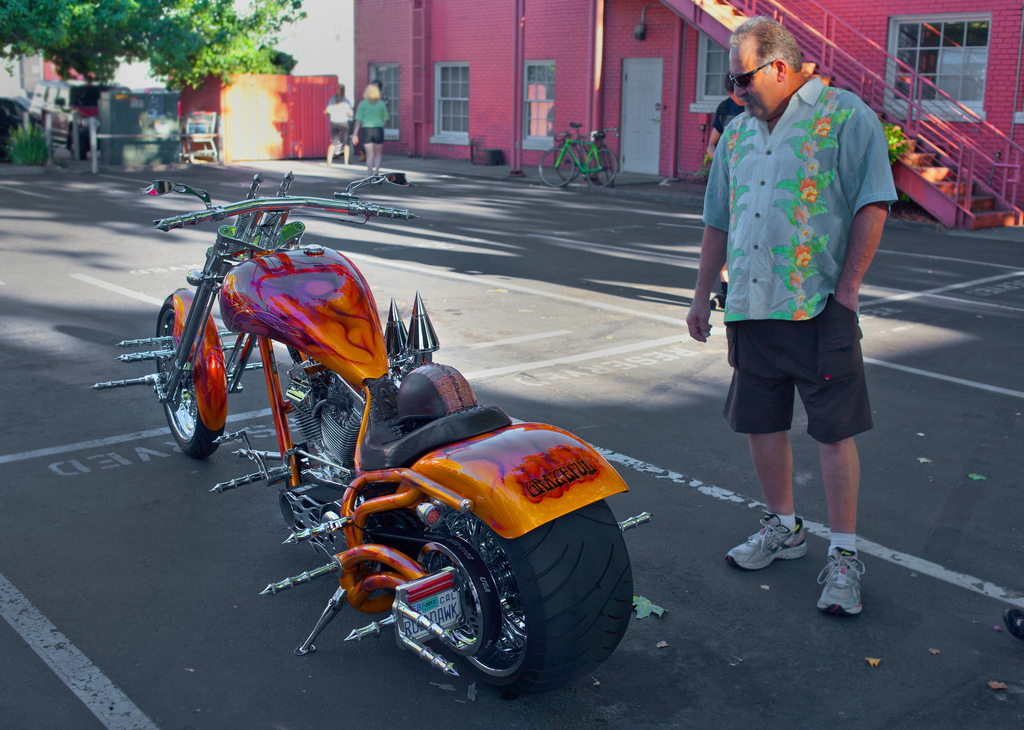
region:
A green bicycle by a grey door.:
[536, 128, 617, 185]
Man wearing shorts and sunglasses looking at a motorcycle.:
[683, 13, 892, 614]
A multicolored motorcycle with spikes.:
[89, 165, 631, 698]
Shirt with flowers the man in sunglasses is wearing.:
[699, 73, 890, 317]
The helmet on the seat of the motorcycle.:
[389, 358, 473, 420]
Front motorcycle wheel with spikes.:
[89, 282, 258, 456]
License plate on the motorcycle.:
[390, 563, 463, 634]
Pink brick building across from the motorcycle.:
[349, 0, 1013, 228]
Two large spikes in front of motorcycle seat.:
[380, 285, 435, 372]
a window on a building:
[369, 63, 398, 130]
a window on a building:
[427, 45, 484, 138]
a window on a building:
[808, 11, 834, 66]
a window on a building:
[894, 30, 983, 111]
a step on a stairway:
[938, 177, 981, 185]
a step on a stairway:
[950, 188, 1001, 205]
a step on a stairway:
[888, 150, 961, 171]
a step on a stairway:
[888, 131, 926, 154]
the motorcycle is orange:
[73, 148, 666, 711]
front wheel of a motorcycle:
[91, 296, 275, 452]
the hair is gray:
[691, 6, 882, 177]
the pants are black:
[651, 12, 909, 633]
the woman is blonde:
[341, 77, 405, 196]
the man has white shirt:
[322, 74, 358, 173]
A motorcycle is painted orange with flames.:
[75, 171, 636, 710]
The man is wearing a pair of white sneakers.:
[682, 493, 894, 645]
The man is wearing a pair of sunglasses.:
[720, 44, 772, 90]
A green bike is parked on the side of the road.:
[540, 116, 636, 194]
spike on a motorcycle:
[264, 559, 332, 607]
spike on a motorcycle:
[344, 602, 392, 647]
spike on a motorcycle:
[254, 557, 340, 602]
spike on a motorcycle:
[279, 515, 327, 553]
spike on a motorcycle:
[211, 461, 282, 504]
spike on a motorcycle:
[236, 437, 282, 460]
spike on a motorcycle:
[204, 414, 239, 446]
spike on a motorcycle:
[88, 365, 168, 408]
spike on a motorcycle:
[116, 344, 173, 370]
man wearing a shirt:
[681, 13, 926, 642]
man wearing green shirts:
[694, 5, 919, 658]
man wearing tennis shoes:
[689, 10, 921, 652]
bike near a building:
[516, 99, 641, 208]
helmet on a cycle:
[383, 349, 472, 452]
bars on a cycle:
[137, 184, 461, 262]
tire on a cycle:
[516, 541, 650, 710]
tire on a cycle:
[125, 267, 233, 460]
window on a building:
[402, 51, 483, 154]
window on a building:
[512, 37, 563, 156]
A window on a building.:
[517, 57, 557, 160]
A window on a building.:
[438, 65, 471, 145]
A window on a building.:
[369, 65, 411, 143]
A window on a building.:
[894, 16, 1022, 116]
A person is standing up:
[705, 35, 912, 655]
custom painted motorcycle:
[80, 165, 643, 703]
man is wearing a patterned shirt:
[678, 11, 901, 625]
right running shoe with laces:
[719, 504, 812, 575]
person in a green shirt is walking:
[343, 77, 392, 192]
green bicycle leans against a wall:
[526, 118, 625, 195]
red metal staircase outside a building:
[667, 1, 1021, 239]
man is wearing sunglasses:
[719, 11, 811, 128]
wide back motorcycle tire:
[402, 485, 643, 708]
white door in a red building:
[608, 52, 672, 186]